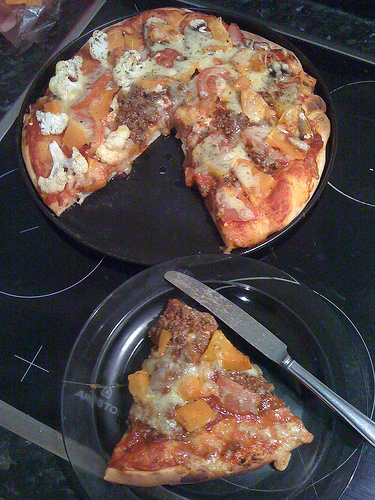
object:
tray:
[17, 7, 339, 271]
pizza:
[19, 7, 330, 252]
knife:
[163, 268, 374, 447]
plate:
[59, 253, 374, 498]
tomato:
[198, 66, 221, 100]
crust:
[103, 426, 312, 484]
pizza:
[103, 299, 312, 484]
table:
[0, 0, 374, 500]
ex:
[14, 345, 48, 382]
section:
[61, 129, 225, 262]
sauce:
[28, 102, 89, 211]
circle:
[1, 168, 108, 299]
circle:
[329, 77, 374, 207]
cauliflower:
[35, 109, 70, 137]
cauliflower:
[36, 141, 88, 194]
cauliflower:
[92, 124, 134, 166]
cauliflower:
[49, 55, 86, 101]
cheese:
[125, 346, 195, 437]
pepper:
[208, 16, 231, 43]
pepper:
[149, 22, 178, 45]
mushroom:
[191, 18, 207, 37]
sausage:
[119, 82, 158, 145]